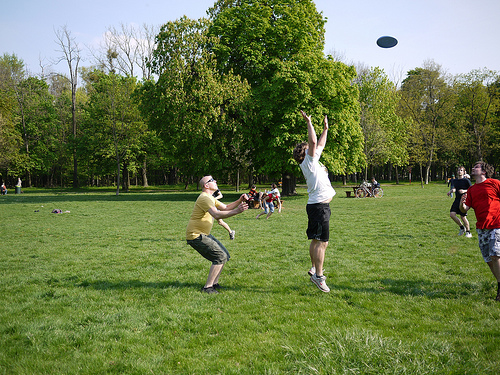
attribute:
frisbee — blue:
[375, 37, 398, 48]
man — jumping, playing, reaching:
[299, 111, 337, 292]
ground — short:
[3, 179, 499, 374]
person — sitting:
[371, 178, 379, 196]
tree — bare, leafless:
[49, 26, 85, 189]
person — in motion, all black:
[446, 164, 473, 240]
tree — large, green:
[198, 2, 328, 192]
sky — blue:
[1, 0, 221, 88]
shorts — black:
[307, 201, 332, 242]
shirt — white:
[299, 151, 335, 205]